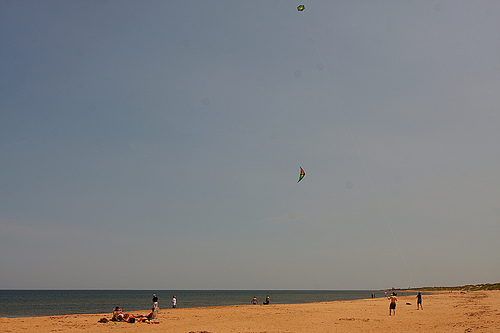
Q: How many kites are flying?
A: 1.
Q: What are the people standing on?
A: Sand.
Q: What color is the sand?
A: Tan.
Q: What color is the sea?
A: Blue.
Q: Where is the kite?
A: In the sky.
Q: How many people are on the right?
A: 2.